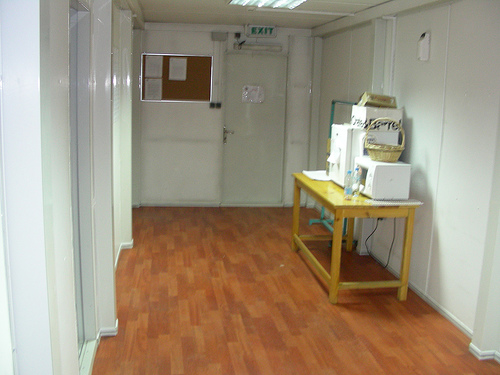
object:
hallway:
[90, 20, 499, 375]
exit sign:
[251, 27, 274, 36]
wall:
[317, 1, 499, 337]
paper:
[417, 33, 430, 60]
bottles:
[344, 171, 353, 200]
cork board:
[142, 55, 212, 101]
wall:
[135, 21, 220, 208]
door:
[223, 49, 289, 207]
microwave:
[353, 156, 410, 200]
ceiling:
[120, 0, 431, 30]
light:
[230, 0, 307, 9]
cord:
[364, 218, 396, 268]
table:
[291, 170, 424, 305]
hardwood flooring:
[93, 207, 499, 375]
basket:
[365, 117, 406, 163]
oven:
[354, 157, 412, 201]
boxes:
[351, 105, 403, 157]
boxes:
[356, 91, 397, 109]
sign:
[251, 27, 273, 35]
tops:
[347, 170, 352, 173]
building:
[0, 0, 496, 375]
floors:
[87, 206, 446, 375]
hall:
[0, 0, 498, 375]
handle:
[223, 126, 236, 144]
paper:
[145, 78, 163, 100]